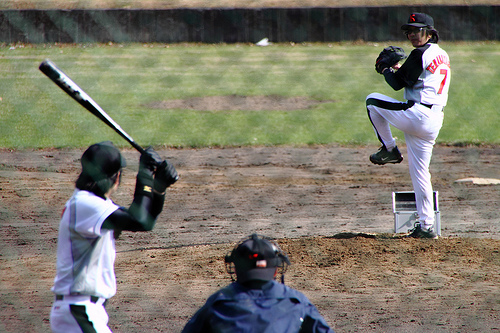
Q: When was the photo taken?
A: Daytime.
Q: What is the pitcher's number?
A: 7.